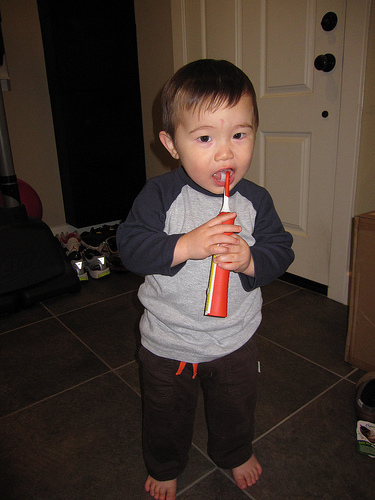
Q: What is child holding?
A: Toothbrush.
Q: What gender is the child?
A: Boy.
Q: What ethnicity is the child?
A: Asian.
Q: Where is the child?
A: Front entry way.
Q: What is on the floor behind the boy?
A: Shoes.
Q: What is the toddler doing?
A: Brushing his teeth.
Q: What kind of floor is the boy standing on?
A: Dark grey tile floor.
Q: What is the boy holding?
A: An electric toothbrush.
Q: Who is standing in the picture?
A: A boy with brown hair.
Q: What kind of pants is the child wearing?
A: Brown pants.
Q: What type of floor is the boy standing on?
A: Brown tiles.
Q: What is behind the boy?
A: A white door.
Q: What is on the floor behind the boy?
A: Tennis shoes.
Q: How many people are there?
A: One.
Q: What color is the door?
A: White.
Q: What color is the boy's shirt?
A: Grey and blue.